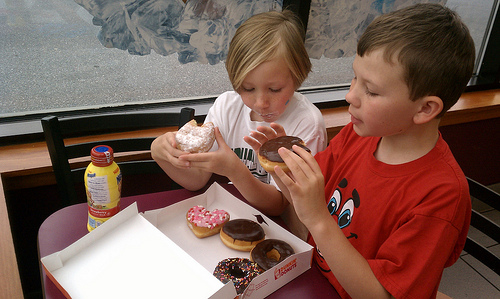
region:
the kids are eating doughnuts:
[111, 33, 428, 248]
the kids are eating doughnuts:
[143, 66, 409, 194]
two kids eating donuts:
[157, 4, 493, 292]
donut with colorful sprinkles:
[209, 248, 264, 293]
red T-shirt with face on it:
[311, 110, 479, 297]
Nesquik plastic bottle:
[71, 134, 137, 235]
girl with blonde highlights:
[211, 7, 326, 119]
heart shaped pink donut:
[181, 198, 230, 240]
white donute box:
[30, 189, 338, 294]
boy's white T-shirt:
[197, 78, 337, 193]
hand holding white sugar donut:
[158, 105, 258, 191]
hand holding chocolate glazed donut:
[247, 122, 337, 217]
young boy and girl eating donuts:
[27, 2, 498, 296]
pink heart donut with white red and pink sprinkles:
[180, 193, 227, 235]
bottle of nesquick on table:
[83, 136, 134, 241]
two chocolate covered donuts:
[226, 208, 304, 267]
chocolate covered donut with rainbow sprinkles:
[212, 254, 263, 296]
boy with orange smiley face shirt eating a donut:
[274, 0, 460, 295]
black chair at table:
[35, 105, 208, 221]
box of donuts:
[50, 172, 331, 296]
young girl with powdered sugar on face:
[221, 14, 333, 154]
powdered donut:
[168, 111, 222, 168]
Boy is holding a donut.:
[258, 4, 460, 296]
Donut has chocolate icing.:
[248, 122, 323, 188]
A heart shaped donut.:
[186, 201, 228, 240]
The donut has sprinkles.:
[184, 200, 228, 239]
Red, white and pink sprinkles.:
[186, 191, 229, 240]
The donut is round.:
[253, 237, 302, 276]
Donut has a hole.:
[249, 235, 299, 273]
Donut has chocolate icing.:
[249, 235, 299, 278]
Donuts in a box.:
[142, 179, 298, 297]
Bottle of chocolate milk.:
[68, 139, 141, 241]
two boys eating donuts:
[147, 0, 472, 295]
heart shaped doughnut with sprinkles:
[185, 202, 230, 237]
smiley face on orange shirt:
[311, 176, 367, 273]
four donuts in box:
[184, 203, 294, 291]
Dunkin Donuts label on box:
[271, 257, 301, 282]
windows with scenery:
[2, 0, 498, 120]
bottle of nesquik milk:
[81, 144, 123, 232]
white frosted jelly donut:
[174, 120, 216, 155]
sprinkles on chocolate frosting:
[216, 254, 263, 291]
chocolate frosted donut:
[251, 238, 294, 270]